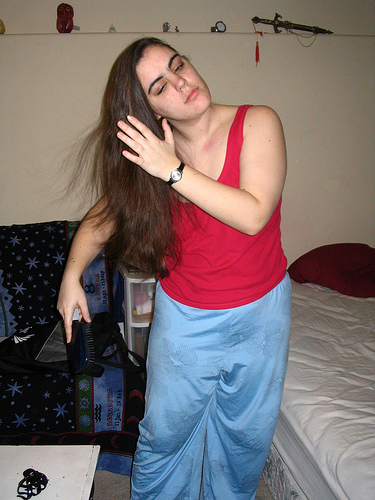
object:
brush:
[68, 308, 96, 376]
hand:
[56, 270, 91, 344]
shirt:
[157, 105, 287, 308]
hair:
[32, 36, 204, 283]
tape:
[15, 466, 48, 500]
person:
[55, 35, 293, 499]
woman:
[56, 35, 291, 500]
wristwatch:
[167, 161, 185, 185]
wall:
[307, 83, 352, 155]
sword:
[251, 12, 335, 69]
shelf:
[11, 30, 43, 40]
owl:
[55, 3, 78, 34]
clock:
[211, 20, 226, 32]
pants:
[130, 273, 296, 500]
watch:
[167, 161, 185, 186]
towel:
[6, 298, 14, 334]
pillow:
[286, 242, 375, 300]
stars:
[25, 257, 40, 269]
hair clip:
[17, 468, 48, 500]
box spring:
[261, 441, 300, 497]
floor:
[107, 477, 124, 495]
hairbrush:
[67, 308, 96, 373]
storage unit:
[128, 278, 156, 323]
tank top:
[226, 245, 263, 270]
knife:
[251, 13, 335, 69]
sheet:
[270, 264, 375, 499]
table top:
[0, 444, 99, 500]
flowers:
[276, 458, 284, 477]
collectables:
[0, 3, 334, 69]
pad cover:
[269, 259, 375, 500]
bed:
[275, 242, 375, 500]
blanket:
[0, 219, 146, 476]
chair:
[0, 220, 146, 477]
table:
[63, 443, 88, 485]